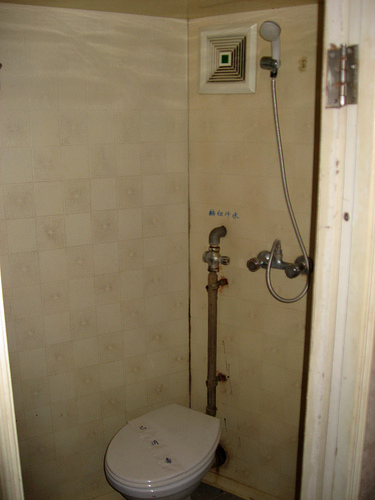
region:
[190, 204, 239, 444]
rusty pipes connected to toilet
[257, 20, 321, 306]
silver shower head hanging on wall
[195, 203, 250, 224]
blue writing on wall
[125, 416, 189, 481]
blue writing on toilet lid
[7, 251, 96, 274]
designs on tiles in bathroom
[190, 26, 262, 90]
vent in wall above toilet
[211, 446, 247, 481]
rust on wall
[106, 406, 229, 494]
old white toilet in bathroom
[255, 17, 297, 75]
white shower head attached to silver piping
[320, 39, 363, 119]
silver hinge leading to bathroom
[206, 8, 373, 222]
a shower head on wall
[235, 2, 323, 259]
a shower head on dirty wall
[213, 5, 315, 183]
a removeable shower head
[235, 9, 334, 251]
a removeable shower head on dirty wall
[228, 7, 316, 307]
a shower head with hose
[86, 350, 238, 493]
a white bathroom toiet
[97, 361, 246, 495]
a dirty bathroom toilet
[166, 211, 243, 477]
a pipe on the wall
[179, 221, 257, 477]
a pipe on a dirty wall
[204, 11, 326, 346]
a showerhead and hose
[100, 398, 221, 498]
Toilet in a bathroom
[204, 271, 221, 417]
Waterpipe for toilet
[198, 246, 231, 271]
Flushing mechanism for toilet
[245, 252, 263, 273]
Hot-water valve for the shower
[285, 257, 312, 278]
Cold water valve for the shower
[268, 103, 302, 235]
Flexible water hose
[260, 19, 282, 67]
Handheld attachment for the shower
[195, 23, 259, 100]
Air vent built into the wall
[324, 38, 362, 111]
Hinge on the door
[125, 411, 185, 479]
Tissue laying on the toilet lid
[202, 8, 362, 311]
a shower head on the wall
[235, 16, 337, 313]
a removable shower head on wall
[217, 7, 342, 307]
a shower head on a hose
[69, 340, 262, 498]
a white bathroom toilet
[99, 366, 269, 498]
a toilet on the wall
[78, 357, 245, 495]
a bathroom toilet on the wall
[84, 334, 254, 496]
a white bathroom toilet on the wall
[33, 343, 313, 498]
a dirty bathroom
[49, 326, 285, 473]
a dirty bathroom toilet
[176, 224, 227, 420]
a pipe on the wall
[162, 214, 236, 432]
Rusty pipe behind the toilet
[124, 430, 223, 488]
Toilet seat is down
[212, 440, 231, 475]
Stain on the wall behind toilet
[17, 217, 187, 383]
Wall has tile design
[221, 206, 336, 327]
controls for a shower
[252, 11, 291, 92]
Shower head hanging up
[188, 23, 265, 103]
Vent on top of wall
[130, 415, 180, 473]
Sign posted on toilet lid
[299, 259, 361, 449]
Door way panel is dirty